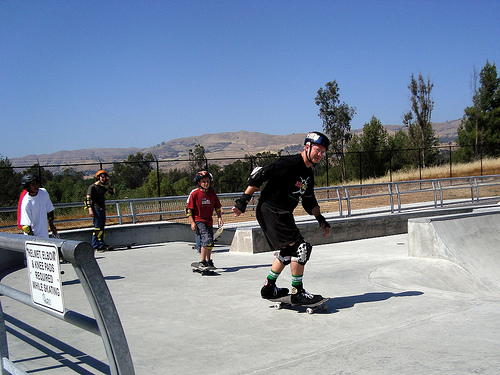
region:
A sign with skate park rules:
[21, 232, 74, 326]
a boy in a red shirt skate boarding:
[187, 165, 234, 286]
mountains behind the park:
[166, 127, 288, 160]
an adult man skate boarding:
[251, 127, 343, 320]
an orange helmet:
[93, 167, 111, 184]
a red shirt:
[186, 185, 227, 230]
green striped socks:
[291, 270, 310, 286]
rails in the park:
[271, 181, 344, 372]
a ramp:
[405, 197, 499, 269]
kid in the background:
[81, 145, 150, 263]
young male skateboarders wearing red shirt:
[181, 185, 226, 222]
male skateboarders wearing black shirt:
[235, 147, 326, 232]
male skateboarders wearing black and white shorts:
[248, 207, 316, 266]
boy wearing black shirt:
[78, 182, 123, 216]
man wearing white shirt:
[6, 190, 63, 227]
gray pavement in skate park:
[358, 206, 491, 360]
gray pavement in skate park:
[130, 278, 256, 364]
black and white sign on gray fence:
[12, 229, 84, 320]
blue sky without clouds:
[6, 13, 306, 115]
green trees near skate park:
[328, 72, 486, 152]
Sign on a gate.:
[20, 242, 72, 319]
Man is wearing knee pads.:
[273, 240, 318, 261]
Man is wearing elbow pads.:
[239, 166, 325, 214]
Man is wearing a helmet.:
[302, 118, 332, 171]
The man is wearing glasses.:
[304, 140, 329, 167]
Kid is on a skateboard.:
[173, 244, 225, 284]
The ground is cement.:
[349, 286, 494, 373]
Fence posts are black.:
[103, 158, 233, 183]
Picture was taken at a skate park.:
[11, 9, 461, 372]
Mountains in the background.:
[21, 15, 252, 111]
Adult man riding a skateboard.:
[226, 105, 343, 317]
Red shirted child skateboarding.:
[183, 157, 228, 277]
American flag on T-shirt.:
[198, 197, 213, 209]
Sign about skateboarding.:
[19, 230, 84, 320]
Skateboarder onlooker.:
[81, 159, 128, 253]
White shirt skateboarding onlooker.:
[0, 155, 80, 285]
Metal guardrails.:
[4, 180, 496, 211]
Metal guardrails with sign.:
[2, 229, 148, 368]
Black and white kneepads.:
[268, 240, 313, 271]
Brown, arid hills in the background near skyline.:
[3, 127, 498, 167]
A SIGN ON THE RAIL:
[8, 232, 72, 322]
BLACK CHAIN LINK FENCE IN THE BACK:
[3, 159, 487, 214]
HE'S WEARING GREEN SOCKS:
[267, 267, 324, 297]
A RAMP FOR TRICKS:
[386, 215, 498, 249]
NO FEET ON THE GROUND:
[246, 273, 348, 328]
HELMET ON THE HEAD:
[298, 127, 338, 170]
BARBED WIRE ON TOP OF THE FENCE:
[12, 153, 160, 166]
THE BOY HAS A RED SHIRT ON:
[188, 186, 237, 231]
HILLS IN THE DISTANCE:
[21, 134, 402, 174]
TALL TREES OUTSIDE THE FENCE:
[286, 68, 496, 141]